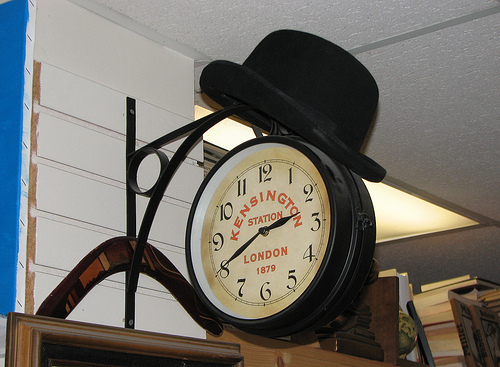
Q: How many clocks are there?
A: One.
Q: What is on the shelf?
A: Books.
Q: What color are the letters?
A: Red.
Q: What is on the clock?
A: Hat.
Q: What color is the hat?
A: Black.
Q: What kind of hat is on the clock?
A: Bowler.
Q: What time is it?
A: 2:40.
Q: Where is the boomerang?
A: On the clock mount.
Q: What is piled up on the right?
A: Books.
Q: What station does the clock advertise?
A: Kensington.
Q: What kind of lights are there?
A: Overhead fluorescent lights.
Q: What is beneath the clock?
A: A wood frame.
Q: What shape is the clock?
A: Round.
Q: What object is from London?
A: The clock.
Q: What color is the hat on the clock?
A: Black.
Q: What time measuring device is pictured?
A: Clock.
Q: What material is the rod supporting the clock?
A: Metal.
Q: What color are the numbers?
A: Black.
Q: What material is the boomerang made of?
A: Wood.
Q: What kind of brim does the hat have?
A: Curled.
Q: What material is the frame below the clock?
A: Wood.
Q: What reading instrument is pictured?
A: Books.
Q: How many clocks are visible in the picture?
A: One.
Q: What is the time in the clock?
A: 2:40 p.m.